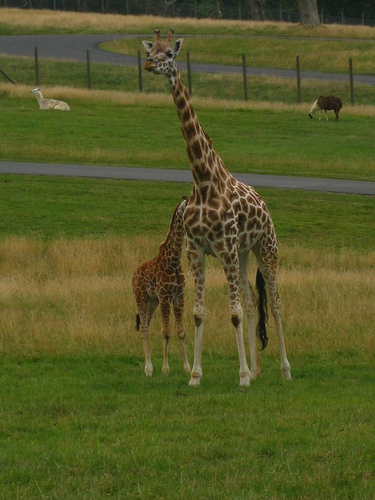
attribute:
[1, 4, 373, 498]
field — grassy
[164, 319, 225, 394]
leg — white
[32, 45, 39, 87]
post — wooden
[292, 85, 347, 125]
llama — multi-colored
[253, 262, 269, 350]
tail — long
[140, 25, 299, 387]
giraffe — adult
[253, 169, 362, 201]
walkway — asphalt, paved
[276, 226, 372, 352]
grass — dried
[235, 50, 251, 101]
post — wooden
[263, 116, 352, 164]
grass — green 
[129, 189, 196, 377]
giraffe — young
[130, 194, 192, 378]
giraffe — young